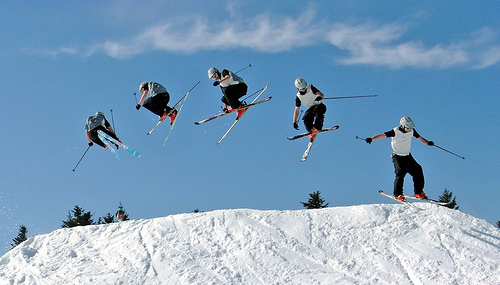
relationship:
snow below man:
[2, 197, 499, 285] [363, 100, 465, 220]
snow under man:
[2, 197, 499, 285] [273, 63, 357, 185]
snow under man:
[2, 197, 499, 285] [193, 55, 277, 152]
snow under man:
[2, 197, 499, 285] [120, 68, 200, 156]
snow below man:
[2, 197, 499, 285] [273, 63, 357, 185]